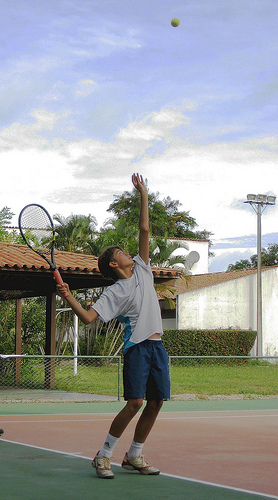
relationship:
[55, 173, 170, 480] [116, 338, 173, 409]
boy wearing blue shorts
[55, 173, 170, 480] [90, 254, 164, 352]
boy wearing a gray shirt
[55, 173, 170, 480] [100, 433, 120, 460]
boy wearing sock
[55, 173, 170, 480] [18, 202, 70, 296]
boy holding racket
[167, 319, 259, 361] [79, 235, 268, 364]
bush by building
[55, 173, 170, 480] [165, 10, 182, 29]
boy serving ball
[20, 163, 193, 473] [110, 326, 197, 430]
boy wearing blue shorts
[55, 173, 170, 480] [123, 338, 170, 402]
boy wearing blue shorts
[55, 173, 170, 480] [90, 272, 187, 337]
boy wearing shirt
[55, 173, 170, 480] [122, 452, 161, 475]
boy wearing shoe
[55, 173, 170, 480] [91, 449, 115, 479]
boy wearing shoe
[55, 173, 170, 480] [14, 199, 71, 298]
boy holding racket